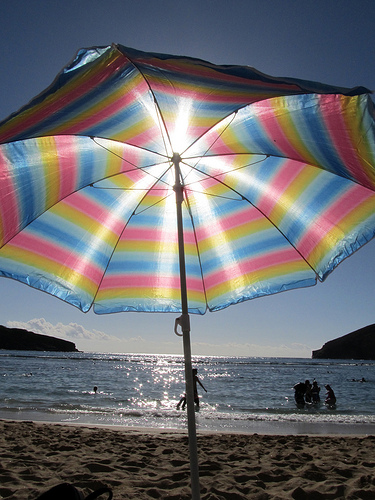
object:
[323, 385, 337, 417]
people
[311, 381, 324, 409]
people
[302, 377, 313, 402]
people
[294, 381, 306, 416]
people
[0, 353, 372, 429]
water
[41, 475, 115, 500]
bag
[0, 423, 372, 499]
sand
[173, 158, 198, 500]
pole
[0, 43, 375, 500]
umbrella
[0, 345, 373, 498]
bay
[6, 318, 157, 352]
clouds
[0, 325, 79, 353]
hill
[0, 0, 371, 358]
sky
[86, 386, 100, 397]
head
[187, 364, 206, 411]
man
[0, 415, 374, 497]
track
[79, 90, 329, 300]
sun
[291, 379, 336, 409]
group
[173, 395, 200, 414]
dog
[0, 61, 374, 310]
rainbow stripes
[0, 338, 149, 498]
left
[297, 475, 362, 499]
rocky cliff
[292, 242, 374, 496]
right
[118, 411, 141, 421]
rock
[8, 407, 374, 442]
shore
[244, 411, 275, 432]
rock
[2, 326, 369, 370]
distance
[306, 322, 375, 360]
rocky oucropping